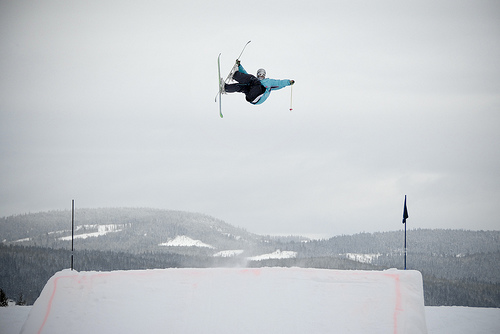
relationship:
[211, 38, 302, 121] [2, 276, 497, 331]
skier in snow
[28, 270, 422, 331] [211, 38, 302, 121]
ramp for skier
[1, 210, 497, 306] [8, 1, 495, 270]
mountains in background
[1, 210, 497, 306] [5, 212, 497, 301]
mountains with trees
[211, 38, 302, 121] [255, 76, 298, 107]
skier wearing jacket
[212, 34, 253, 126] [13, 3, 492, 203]
skis in air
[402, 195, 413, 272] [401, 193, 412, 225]
pole has flag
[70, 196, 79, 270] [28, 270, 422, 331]
pole on ramp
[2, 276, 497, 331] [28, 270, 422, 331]
snow on ramp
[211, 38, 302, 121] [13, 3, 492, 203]
skier in air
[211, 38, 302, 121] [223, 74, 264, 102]
skier wears pants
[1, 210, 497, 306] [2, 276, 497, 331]
mountains have snow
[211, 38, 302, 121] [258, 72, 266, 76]
skier wearing goggles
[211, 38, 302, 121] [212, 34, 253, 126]
skier on skis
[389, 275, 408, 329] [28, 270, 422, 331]
line on ramp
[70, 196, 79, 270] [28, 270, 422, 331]
pole behind ramp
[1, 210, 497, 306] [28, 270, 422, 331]
mountains behind ramp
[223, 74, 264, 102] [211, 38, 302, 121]
pants on skier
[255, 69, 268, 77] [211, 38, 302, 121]
helmet on skier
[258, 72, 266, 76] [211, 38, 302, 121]
goggles on skier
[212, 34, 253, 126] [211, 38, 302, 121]
skis on skier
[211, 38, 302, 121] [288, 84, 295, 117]
skier has ski pole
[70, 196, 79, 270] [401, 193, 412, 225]
pole with flag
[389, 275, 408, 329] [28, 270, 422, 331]
line around ramp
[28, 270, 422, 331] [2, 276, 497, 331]
ramp covered in snow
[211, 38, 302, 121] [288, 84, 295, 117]
skier holds ski pole